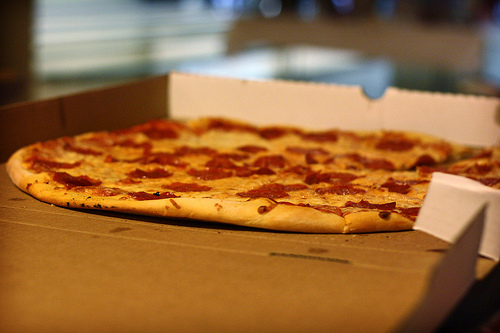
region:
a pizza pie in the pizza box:
[6, 116, 499, 232]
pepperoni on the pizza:
[53, 170, 100, 190]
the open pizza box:
[1, 233, 498, 331]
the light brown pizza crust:
[116, 199, 258, 226]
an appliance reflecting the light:
[31, 1, 226, 73]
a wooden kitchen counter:
[232, 0, 499, 83]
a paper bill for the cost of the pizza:
[415, 171, 499, 261]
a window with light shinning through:
[33, 1, 226, 77]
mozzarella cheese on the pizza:
[205, 131, 244, 148]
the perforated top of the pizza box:
[169, 67, 499, 99]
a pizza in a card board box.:
[9, 114, 499, 232]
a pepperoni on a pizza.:
[155, 177, 232, 201]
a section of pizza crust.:
[161, 193, 346, 240]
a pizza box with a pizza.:
[169, 67, 499, 151]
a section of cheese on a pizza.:
[209, 173, 245, 194]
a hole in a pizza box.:
[261, 237, 370, 272]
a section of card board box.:
[161, 62, 498, 128]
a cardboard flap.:
[406, 199, 488, 316]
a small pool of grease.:
[94, 220, 159, 262]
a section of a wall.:
[238, 3, 483, 68]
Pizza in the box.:
[11, 45, 491, 314]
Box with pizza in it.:
[19, 102, 461, 297]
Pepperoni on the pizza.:
[57, 66, 459, 275]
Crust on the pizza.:
[112, 122, 254, 280]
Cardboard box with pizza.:
[162, 45, 471, 246]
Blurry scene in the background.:
[180, 18, 423, 99]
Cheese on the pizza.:
[71, 60, 375, 269]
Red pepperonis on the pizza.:
[180, 111, 385, 241]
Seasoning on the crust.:
[17, 162, 134, 225]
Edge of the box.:
[373, 167, 498, 269]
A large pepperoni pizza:
[22, 121, 465, 236]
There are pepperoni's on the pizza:
[198, 127, 382, 204]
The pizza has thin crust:
[123, 192, 380, 244]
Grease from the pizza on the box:
[96, 215, 157, 250]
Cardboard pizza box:
[46, 236, 244, 324]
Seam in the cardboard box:
[107, 218, 467, 293]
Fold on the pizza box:
[419, 162, 497, 277]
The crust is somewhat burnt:
[252, 188, 334, 233]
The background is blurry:
[232, 4, 498, 69]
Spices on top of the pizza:
[148, 185, 161, 198]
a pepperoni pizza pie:
[18, 106, 497, 236]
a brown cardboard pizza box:
[3, 63, 495, 330]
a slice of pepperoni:
[238, 185, 278, 200]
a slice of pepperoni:
[163, 179, 211, 196]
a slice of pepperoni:
[128, 165, 168, 180]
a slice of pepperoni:
[53, 168, 102, 188]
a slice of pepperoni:
[138, 154, 186, 167]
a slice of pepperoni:
[168, 141, 215, 156]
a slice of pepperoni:
[140, 126, 174, 140]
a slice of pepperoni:
[232, 139, 262, 154]